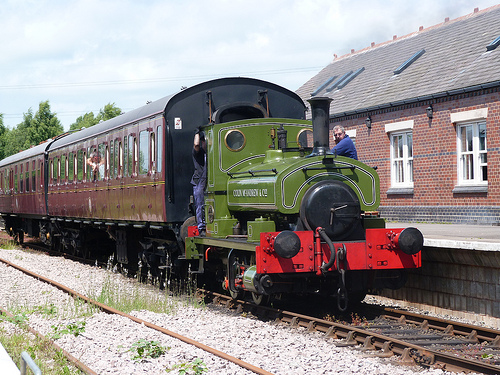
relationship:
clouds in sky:
[83, 1, 436, 96] [5, 4, 499, 139]